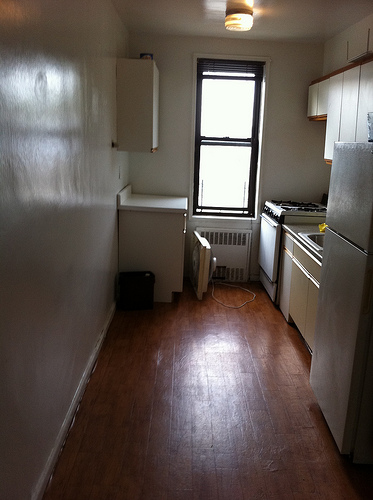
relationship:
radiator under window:
[185, 221, 254, 282] [198, 66, 256, 214]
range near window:
[255, 197, 326, 304] [198, 66, 256, 214]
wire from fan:
[211, 281, 257, 309] [189, 228, 216, 300]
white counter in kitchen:
[119, 193, 188, 215] [73, 29, 360, 465]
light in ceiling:
[220, 9, 257, 31] [120, 5, 362, 39]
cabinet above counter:
[121, 50, 179, 168] [117, 178, 196, 234]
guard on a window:
[200, 180, 251, 213] [194, 57, 266, 216]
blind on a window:
[189, 53, 291, 99] [192, 55, 268, 233]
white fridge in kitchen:
[307, 141, 369, 455] [2, 2, 370, 496]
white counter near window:
[116, 183, 188, 303] [194, 57, 266, 216]